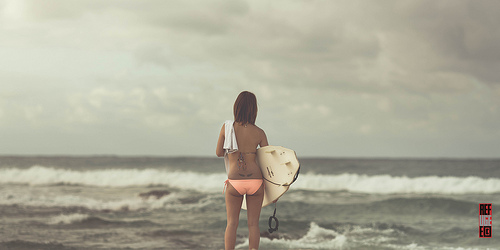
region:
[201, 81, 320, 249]
woman holding surfboard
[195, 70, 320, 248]
holding board facing water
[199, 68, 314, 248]
girl wearing a bikini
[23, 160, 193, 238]
choppy water and waves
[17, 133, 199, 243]
surf breaking near beach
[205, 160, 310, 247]
pick bikini bottom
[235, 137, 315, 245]
surfboard with leash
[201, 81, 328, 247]
girl with shirt over her shoulder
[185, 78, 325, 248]
girl with short hair facing away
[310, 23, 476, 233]
overcast weather at shore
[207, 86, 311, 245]
a woman holding a surfboard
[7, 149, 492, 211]
a wave in the ocean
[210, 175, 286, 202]
peach colored bikini bottom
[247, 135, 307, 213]
the surfboard is white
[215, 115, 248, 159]
towel draped over woman's shoulder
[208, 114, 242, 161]
the towel is white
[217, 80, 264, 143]
the woman has dark colored hair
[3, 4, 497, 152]
the sky is gray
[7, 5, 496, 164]
the sky is cloudy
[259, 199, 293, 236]
tether hanging from surfboard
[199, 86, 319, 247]
A woman holding a surfboard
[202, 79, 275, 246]
A woman in a bikini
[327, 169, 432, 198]
White caps on waves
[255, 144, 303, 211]
A white surfboard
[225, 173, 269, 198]
Peach colored bikini bottoms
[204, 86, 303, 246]
Back view of a woman holding a surfboard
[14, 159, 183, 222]
Waves crashing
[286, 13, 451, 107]
Clouds in the sky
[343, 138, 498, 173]
Water meeting the horizon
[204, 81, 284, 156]
Woman with something white draped on her shoulder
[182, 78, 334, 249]
woman standing on the beach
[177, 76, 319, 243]
woman holding a surfboard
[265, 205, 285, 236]
black strap hanging down from the surfboard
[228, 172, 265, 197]
light pink bikini bottoms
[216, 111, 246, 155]
white fabric hanging over the shoulder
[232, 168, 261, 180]
tattoo on the lower back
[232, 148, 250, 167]
strings of the bikini hanging down the back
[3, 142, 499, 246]
body of water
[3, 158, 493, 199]
long wave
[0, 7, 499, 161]
sky is cloudy and gray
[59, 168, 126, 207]
Ocean waves and surf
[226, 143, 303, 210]
A surfboard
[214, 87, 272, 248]
A woman looking out at the ocean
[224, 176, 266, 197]
A womans swimsuit bottoms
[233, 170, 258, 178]
A tattoo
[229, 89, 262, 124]
Brunette straight hair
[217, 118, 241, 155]
A white beach towel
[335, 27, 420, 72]
Grey puffy overcast clouds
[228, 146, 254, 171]
Womans swimsuit top straps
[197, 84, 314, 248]
Surfer girl standing before the ocean